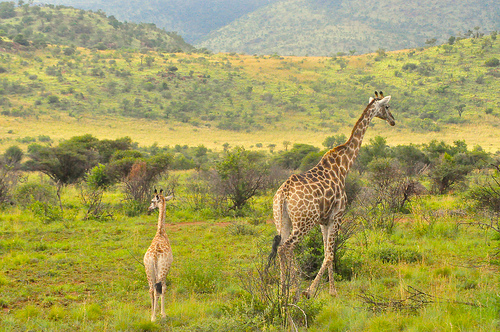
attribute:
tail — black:
[265, 194, 287, 272]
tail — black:
[151, 246, 163, 293]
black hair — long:
[264, 232, 284, 272]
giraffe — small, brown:
[140, 186, 175, 321]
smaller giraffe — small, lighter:
[143, 184, 175, 322]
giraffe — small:
[123, 180, 192, 328]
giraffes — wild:
[272, 88, 396, 300]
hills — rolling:
[2, 0, 496, 147]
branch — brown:
[361, 277, 483, 312]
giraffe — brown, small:
[136, 190, 177, 318]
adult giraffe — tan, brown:
[263, 89, 396, 311]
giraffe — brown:
[267, 91, 394, 323]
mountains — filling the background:
[113, 11, 394, 131]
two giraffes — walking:
[138, 87, 400, 323]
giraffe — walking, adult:
[266, 90, 397, 299]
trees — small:
[41, 51, 376, 261]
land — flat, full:
[7, 124, 498, 329]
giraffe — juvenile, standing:
[128, 182, 186, 325]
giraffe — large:
[248, 82, 406, 309]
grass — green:
[0, 1, 494, 326]